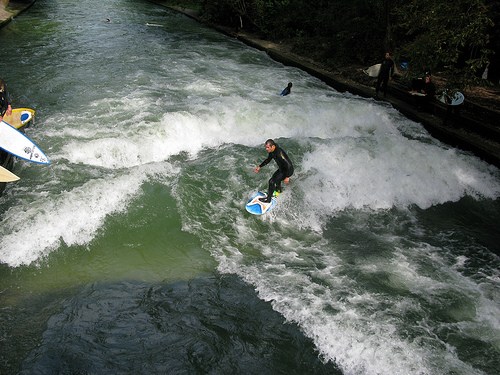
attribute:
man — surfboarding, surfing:
[252, 131, 294, 203]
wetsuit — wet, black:
[267, 151, 290, 195]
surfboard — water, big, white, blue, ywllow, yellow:
[225, 173, 291, 218]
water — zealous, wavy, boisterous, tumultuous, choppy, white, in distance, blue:
[8, 47, 460, 275]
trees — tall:
[239, 0, 488, 78]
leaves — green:
[431, 18, 463, 51]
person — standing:
[375, 49, 397, 97]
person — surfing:
[208, 125, 319, 257]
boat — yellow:
[2, 105, 40, 131]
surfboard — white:
[1, 119, 52, 168]